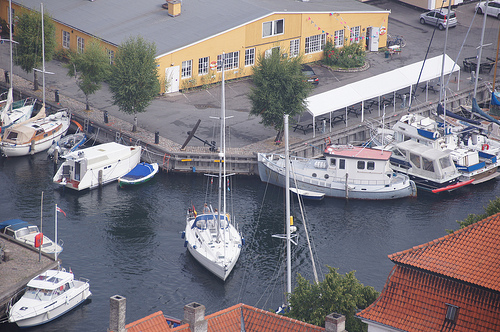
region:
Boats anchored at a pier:
[268, 81, 498, 202]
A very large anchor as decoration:
[175, 120, 217, 149]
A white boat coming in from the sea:
[182, 188, 250, 278]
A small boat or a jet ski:
[118, 149, 168, 196]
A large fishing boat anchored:
[246, 137, 435, 213]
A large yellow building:
[157, 7, 386, 69]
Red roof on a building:
[381, 229, 481, 317]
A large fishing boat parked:
[243, 142, 411, 189]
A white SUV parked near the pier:
[415, 2, 468, 26]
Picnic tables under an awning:
[288, 102, 388, 137]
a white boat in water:
[184, 54, 244, 289]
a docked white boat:
[4, 265, 93, 327]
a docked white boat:
[0, 215, 64, 258]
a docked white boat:
[116, 158, 158, 187]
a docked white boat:
[51, 138, 141, 190]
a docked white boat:
[2, 107, 75, 157]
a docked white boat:
[256, 141, 423, 201]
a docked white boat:
[369, 138, 458, 195]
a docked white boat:
[372, 111, 497, 184]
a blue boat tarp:
[124, 161, 154, 176]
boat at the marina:
[170, 198, 242, 289]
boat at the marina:
[6, 291, 96, 319]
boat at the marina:
[108, 158, 164, 184]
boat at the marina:
[1, 220, 76, 256]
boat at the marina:
[63, 155, 125, 184]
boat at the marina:
[42, 132, 83, 154]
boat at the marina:
[9, 118, 61, 139]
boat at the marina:
[251, 142, 431, 204]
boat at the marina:
[396, 139, 451, 191]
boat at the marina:
[454, 136, 488, 179]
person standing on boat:
[185, 205, 212, 227]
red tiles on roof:
[398, 287, 420, 311]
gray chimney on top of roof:
[173, 292, 211, 315]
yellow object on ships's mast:
[279, 208, 299, 225]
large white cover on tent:
[303, 59, 493, 94]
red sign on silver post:
[22, 222, 59, 266]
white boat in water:
[2, 269, 98, 318]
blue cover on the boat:
[120, 160, 164, 182]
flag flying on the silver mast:
[50, 199, 82, 228]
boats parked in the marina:
[17, 88, 459, 237]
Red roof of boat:
[321, 138, 395, 165]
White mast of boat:
[207, 65, 237, 242]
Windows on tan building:
[177, 22, 367, 87]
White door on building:
[161, 62, 184, 98]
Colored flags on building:
[301, 3, 359, 48]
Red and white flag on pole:
[49, 197, 74, 217]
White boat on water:
[170, 197, 255, 293]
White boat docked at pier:
[45, 137, 150, 198]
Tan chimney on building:
[158, 0, 187, 18]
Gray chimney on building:
[98, 287, 140, 330]